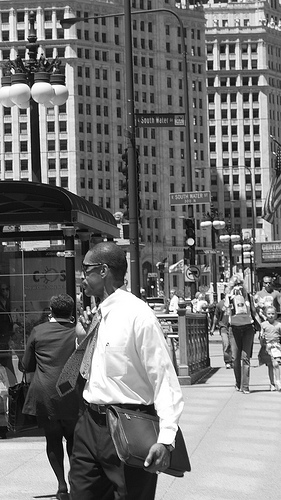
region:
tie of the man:
[57, 311, 99, 397]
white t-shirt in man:
[75, 289, 176, 444]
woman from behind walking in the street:
[20, 296, 89, 499]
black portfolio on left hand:
[106, 403, 189, 476]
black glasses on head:
[82, 261, 104, 269]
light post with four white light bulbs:
[0, 51, 68, 192]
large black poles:
[116, 0, 258, 341]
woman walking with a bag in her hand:
[223, 273, 280, 386]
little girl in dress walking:
[257, 301, 279, 388]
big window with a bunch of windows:
[0, 4, 208, 357]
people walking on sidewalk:
[201, 270, 280, 403]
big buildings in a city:
[0, 53, 77, 171]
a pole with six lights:
[1, 56, 77, 179]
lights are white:
[0, 80, 74, 112]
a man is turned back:
[44, 238, 195, 498]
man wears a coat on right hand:
[50, 238, 196, 497]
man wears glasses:
[68, 235, 140, 313]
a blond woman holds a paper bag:
[219, 267, 261, 397]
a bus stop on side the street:
[2, 177, 116, 436]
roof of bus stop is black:
[1, 172, 126, 241]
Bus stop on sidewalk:
[0, 177, 123, 358]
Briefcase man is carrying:
[103, 402, 196, 481]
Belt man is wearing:
[83, 398, 158, 422]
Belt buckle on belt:
[92, 402, 109, 417]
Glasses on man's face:
[77, 259, 105, 277]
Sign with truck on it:
[183, 262, 207, 284]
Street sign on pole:
[133, 109, 190, 131]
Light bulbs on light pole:
[0, 74, 73, 119]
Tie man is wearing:
[50, 313, 104, 400]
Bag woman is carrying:
[224, 288, 247, 321]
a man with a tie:
[34, 220, 197, 499]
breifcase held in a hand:
[93, 391, 205, 486]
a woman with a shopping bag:
[217, 265, 262, 389]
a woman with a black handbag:
[10, 290, 85, 499]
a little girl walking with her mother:
[252, 300, 280, 401]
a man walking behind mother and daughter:
[253, 272, 279, 318]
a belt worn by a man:
[82, 396, 157, 420]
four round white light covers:
[0, 83, 73, 115]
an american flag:
[263, 137, 279, 225]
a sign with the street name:
[134, 103, 199, 132]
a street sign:
[167, 188, 211, 205]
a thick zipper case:
[104, 401, 189, 478]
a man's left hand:
[139, 440, 172, 474]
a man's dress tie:
[54, 301, 102, 399]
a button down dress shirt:
[74, 287, 185, 450]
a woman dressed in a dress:
[7, 293, 90, 488]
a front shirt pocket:
[102, 341, 129, 375]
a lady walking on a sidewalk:
[219, 270, 260, 394]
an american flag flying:
[259, 141, 279, 222]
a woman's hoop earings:
[45, 310, 78, 324]